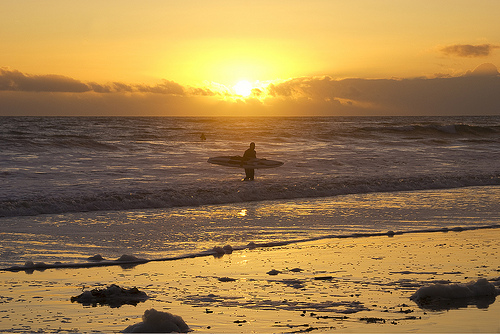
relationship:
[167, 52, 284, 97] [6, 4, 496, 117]
sun in thehorizon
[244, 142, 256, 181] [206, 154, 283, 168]
man has surfboard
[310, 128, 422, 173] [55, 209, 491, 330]
water on sand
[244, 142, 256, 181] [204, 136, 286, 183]
man carry surfboard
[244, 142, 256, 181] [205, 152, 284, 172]
man carry surfboard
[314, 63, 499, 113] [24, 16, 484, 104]
clouds in sky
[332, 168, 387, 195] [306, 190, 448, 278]
wave in beach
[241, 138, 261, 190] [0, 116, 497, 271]
man in water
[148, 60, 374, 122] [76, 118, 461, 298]
sunset in beach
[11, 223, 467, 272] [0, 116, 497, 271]
foam in water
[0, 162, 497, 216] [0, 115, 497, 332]
ripples in water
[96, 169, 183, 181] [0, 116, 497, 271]
ripple in water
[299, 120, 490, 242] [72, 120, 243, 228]
ripples in water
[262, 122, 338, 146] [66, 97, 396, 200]
ripples in water